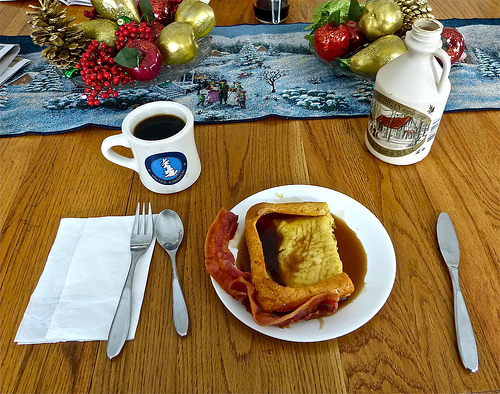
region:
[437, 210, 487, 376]
a knife of a table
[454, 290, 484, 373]
the handle of a knife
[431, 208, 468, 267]
the cutting part of a knife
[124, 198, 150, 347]
a fork of a table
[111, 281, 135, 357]
the handle of a fork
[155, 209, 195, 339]
a tea spoon on the table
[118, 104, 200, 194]
a cup on the table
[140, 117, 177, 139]
coffee in a cup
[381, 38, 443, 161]
a bottle on the table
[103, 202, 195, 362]
The silverware is on the table.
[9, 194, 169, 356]
The napkin is white.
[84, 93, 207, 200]
The mug is white.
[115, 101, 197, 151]
Coffee is in the mug.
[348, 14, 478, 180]
The syrup is on the table.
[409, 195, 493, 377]
The knife is silver.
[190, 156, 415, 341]
The syrup is on the french toast.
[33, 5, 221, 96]
The center piece is on the table.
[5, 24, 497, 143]
The table runner is blue.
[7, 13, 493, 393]
The table is brown.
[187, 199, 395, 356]
food on the plate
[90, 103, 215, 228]
a cup of coffee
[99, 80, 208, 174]
a cup of coffee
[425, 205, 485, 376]
Knife on a table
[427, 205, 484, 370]
Knife is on a table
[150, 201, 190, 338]
Spoon on a table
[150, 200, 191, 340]
Spoon is on a table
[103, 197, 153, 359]
Fork on a table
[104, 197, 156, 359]
Fork is on a table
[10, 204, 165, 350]
Napkin on a table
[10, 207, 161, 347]
Napkin is on a table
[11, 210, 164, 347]
Paper napkin on a table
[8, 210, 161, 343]
Paper napkin is on a table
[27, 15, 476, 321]
a breakfast on the table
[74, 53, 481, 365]
this breakfast is for one person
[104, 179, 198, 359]
a fork and spoon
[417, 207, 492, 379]
a knife on the table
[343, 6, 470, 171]
a jug with the meal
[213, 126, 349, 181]
the table is wooden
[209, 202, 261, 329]
bacon on the plate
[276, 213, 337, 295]
french toast on the plate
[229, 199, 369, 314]
syrup on the french toast